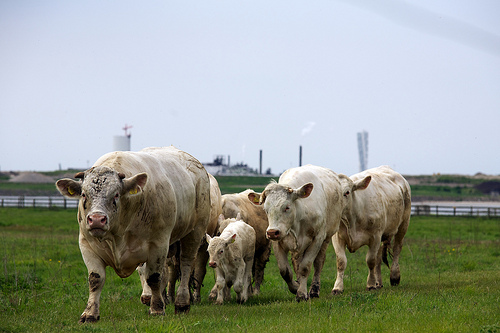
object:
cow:
[54, 144, 213, 325]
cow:
[247, 163, 344, 304]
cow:
[331, 164, 413, 293]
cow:
[134, 171, 223, 308]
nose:
[86, 213, 109, 230]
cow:
[204, 219, 256, 303]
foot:
[214, 298, 225, 305]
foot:
[235, 295, 246, 305]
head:
[55, 165, 149, 238]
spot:
[82, 197, 87, 210]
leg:
[78, 244, 106, 323]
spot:
[88, 271, 102, 292]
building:
[200, 149, 277, 177]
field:
[1, 206, 499, 331]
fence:
[0, 195, 499, 219]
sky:
[1, 2, 499, 178]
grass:
[0, 164, 500, 201]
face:
[206, 245, 226, 269]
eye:
[80, 191, 88, 198]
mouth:
[85, 226, 110, 234]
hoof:
[79, 312, 100, 324]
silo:
[112, 123, 134, 152]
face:
[79, 188, 123, 237]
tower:
[355, 129, 370, 173]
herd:
[245, 179, 317, 241]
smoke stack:
[258, 149, 264, 175]